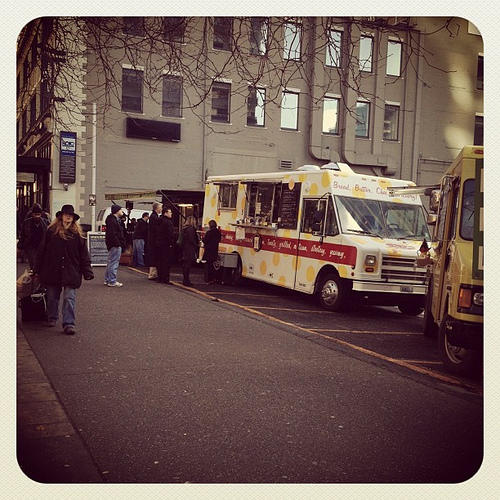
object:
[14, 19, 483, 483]
scene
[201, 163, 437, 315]
truck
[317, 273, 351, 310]
front wheel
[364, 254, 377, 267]
front headlight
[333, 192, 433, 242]
front windshield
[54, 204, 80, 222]
black hat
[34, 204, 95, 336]
walking person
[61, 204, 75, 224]
head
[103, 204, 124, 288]
man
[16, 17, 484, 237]
building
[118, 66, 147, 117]
windows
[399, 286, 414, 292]
license plate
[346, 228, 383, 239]
windshield wiper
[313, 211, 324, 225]
side view mirror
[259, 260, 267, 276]
polka dots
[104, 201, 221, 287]
crowd of people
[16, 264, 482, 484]
road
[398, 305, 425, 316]
tire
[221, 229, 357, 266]
stripe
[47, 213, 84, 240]
long blonde hair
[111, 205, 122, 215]
beanie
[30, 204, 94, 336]
woman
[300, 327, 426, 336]
lines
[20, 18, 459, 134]
tree branches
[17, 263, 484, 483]
walkway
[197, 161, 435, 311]
2 parked food trucks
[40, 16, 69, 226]
corner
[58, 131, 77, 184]
sign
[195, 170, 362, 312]
side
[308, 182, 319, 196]
dot